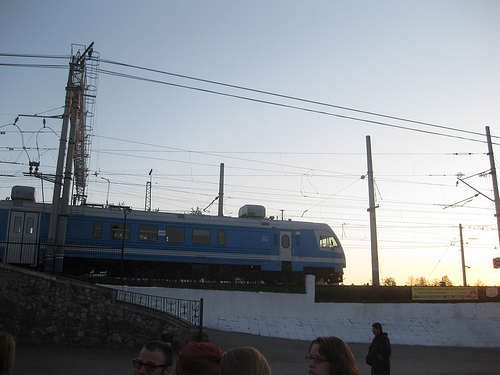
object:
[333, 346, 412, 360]
ground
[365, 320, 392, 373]
man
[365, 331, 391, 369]
clothing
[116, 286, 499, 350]
wall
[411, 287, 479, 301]
sign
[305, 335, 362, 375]
woman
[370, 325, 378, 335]
face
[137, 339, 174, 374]
man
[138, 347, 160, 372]
face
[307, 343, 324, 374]
face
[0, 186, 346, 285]
train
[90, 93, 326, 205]
wires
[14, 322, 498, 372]
walkway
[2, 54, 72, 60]
wire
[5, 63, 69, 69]
wire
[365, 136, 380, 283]
electric pole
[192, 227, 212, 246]
window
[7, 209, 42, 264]
train door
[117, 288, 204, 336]
fence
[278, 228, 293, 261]
door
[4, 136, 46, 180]
wires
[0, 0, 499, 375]
air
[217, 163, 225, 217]
pole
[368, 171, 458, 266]
polewires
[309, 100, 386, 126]
power lines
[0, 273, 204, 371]
train stop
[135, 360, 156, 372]
sunglasses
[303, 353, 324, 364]
glasses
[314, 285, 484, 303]
concrete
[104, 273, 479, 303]
track